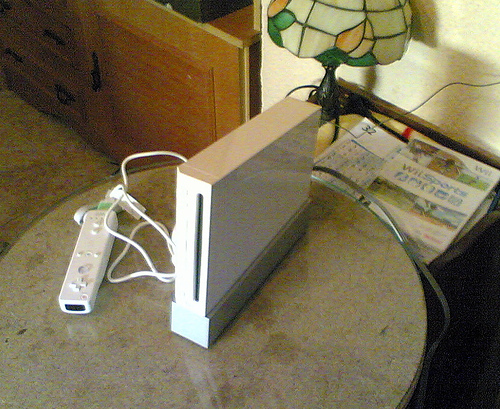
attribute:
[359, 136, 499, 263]
book — white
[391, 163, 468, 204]
text — blue 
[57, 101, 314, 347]
game — unplugged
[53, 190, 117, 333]
remote — round 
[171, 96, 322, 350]
wii — white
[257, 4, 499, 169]
wall — cream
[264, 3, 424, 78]
lamp shade — stained glass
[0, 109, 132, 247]
carpet — tan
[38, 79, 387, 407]
wii — white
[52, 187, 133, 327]
remote — white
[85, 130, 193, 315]
cord — white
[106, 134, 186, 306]
cord — tangled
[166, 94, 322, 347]
wii console — round 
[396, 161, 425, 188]
print — gray 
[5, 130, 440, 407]
table — small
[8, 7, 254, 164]
cabinets — wooden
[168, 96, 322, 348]
nintendo wii — white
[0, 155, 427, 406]
table — round 